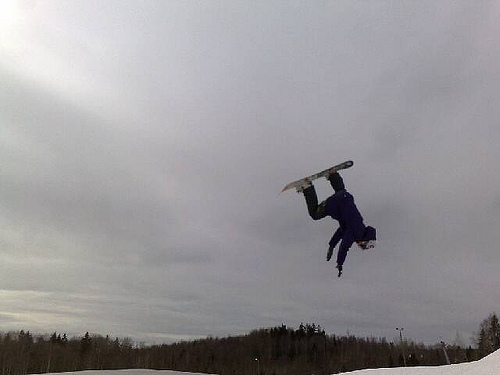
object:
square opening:
[310, 176, 335, 207]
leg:
[303, 189, 329, 221]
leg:
[329, 177, 344, 194]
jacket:
[324, 202, 376, 271]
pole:
[394, 325, 409, 365]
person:
[294, 171, 379, 280]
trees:
[75, 327, 93, 371]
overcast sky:
[0, 0, 497, 349]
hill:
[0, 316, 499, 374]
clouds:
[0, 0, 499, 351]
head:
[355, 223, 378, 253]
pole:
[436, 338, 451, 366]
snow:
[8, 349, 500, 375]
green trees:
[474, 308, 500, 361]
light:
[0, 0, 164, 142]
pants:
[298, 170, 355, 222]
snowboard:
[280, 160, 354, 194]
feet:
[295, 179, 311, 193]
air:
[0, 0, 498, 160]